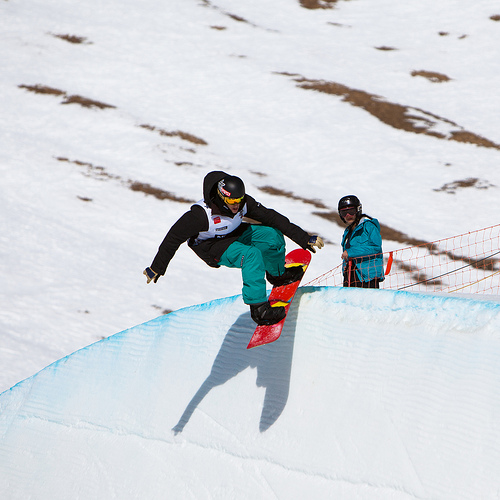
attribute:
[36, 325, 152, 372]
ice — blue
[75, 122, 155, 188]
mark — brown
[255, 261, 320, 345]
snowboard — red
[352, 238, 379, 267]
jacket — blue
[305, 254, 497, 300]
net — orange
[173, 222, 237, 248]
jacket — black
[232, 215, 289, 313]
ski pants — aqua 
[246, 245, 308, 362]
snow board — red, yellow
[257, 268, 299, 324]
ski boots — black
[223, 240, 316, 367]
snowboard — red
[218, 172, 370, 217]
helmets — black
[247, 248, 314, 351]
snowboard — red, yellow, reddish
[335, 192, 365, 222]
helmet — black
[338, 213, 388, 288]
coat — green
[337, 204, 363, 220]
goggles — black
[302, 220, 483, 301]
net — orange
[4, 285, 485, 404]
line — blue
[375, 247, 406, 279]
ribbon — orange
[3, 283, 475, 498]
hill — snowy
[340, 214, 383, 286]
jacket — blue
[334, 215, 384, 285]
jacket — blue, large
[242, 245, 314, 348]
snowboard — red